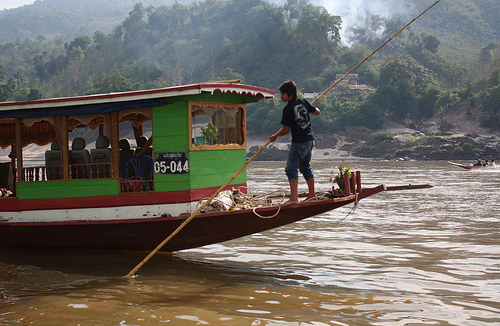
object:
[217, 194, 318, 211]
space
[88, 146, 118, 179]
seat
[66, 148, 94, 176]
seat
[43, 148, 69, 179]
seat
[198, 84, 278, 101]
trim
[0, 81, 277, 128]
roof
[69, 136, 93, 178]
people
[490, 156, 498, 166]
people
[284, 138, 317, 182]
pants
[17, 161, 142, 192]
seating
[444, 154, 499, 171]
boat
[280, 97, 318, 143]
tee shirt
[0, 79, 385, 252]
boat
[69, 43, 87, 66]
trees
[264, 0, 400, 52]
smoke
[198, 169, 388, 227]
boat deck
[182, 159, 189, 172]
numbers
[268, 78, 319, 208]
boy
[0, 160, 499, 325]
water